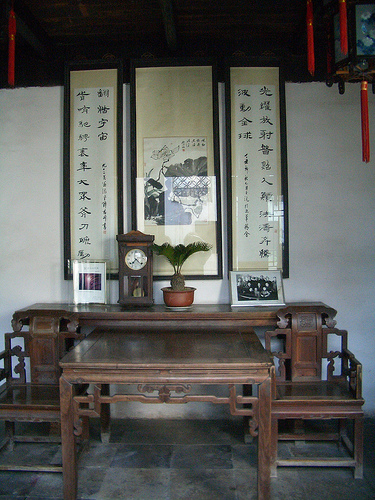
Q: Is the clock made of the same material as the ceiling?
A: Yes, both the clock and the ceiling are made of wood.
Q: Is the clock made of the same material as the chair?
A: Yes, both the clock and the chair are made of wood.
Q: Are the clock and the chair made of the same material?
A: Yes, both the clock and the chair are made of wood.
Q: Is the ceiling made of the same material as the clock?
A: Yes, both the ceiling and the clock are made of wood.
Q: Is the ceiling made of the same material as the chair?
A: Yes, both the ceiling and the chair are made of wood.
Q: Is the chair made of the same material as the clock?
A: Yes, both the chair and the clock are made of wood.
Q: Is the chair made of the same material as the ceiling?
A: Yes, both the chair and the ceiling are made of wood.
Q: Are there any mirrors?
A: No, there are no mirrors.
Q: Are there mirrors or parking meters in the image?
A: No, there are no mirrors or parking meters.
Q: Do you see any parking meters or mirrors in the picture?
A: No, there are no mirrors or parking meters.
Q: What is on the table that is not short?
A: The plant is on the table.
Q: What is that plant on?
A: The plant is on the table.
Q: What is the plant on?
A: The plant is on the table.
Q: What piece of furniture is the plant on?
A: The plant is on the table.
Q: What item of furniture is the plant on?
A: The plant is on the table.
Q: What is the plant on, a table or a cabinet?
A: The plant is on a table.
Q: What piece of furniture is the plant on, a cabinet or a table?
A: The plant is on a table.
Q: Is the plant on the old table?
A: Yes, the plant is on the table.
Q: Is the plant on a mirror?
A: No, the plant is on the table.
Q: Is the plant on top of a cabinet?
A: No, the plant is on top of a table.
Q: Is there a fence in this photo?
A: No, there are no fences.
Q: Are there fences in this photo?
A: No, there are no fences.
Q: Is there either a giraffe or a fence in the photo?
A: No, there are no fences or giraffes.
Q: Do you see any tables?
A: Yes, there is a table.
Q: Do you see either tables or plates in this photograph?
A: Yes, there is a table.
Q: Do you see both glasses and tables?
A: No, there is a table but no glasses.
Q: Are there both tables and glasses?
A: No, there is a table but no glasses.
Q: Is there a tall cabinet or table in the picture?
A: Yes, there is a tall table.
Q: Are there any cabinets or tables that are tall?
A: Yes, the table is tall.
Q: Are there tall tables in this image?
A: Yes, there is a tall table.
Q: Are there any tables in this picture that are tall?
A: Yes, there is a table that is tall.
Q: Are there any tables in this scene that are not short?
A: Yes, there is a tall table.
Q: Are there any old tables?
A: Yes, there is an old table.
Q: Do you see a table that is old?
A: Yes, there is a table that is old.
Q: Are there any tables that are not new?
A: Yes, there is a old table.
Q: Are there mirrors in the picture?
A: No, there are no mirrors.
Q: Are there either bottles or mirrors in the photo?
A: No, there are no mirrors or bottles.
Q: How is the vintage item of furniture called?
A: The piece of furniture is a table.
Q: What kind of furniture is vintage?
A: The furniture is a table.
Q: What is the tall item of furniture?
A: The piece of furniture is a table.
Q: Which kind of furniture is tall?
A: The furniture is a table.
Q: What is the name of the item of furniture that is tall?
A: The piece of furniture is a table.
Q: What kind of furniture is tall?
A: The furniture is a table.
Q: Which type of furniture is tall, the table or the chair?
A: The table is tall.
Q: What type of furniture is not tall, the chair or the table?
A: The chair is not tall.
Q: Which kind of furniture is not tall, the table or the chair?
A: The chair is not tall.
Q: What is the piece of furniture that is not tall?
A: The piece of furniture is a chair.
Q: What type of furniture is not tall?
A: The furniture is a chair.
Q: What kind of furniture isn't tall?
A: The furniture is a chair.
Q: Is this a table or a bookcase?
A: This is a table.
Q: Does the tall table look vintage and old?
A: Yes, the table is vintage and old.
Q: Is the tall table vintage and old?
A: Yes, the table is vintage and old.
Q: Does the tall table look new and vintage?
A: No, the table is vintage but old.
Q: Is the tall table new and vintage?
A: No, the table is vintage but old.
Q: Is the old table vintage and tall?
A: Yes, the table is vintage and tall.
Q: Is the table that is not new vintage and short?
A: No, the table is vintage but tall.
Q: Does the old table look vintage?
A: Yes, the table is vintage.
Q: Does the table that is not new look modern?
A: No, the table is vintage.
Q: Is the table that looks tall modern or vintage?
A: The table is vintage.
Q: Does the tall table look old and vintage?
A: Yes, the table is old and vintage.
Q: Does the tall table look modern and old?
A: No, the table is old but vintage.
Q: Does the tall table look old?
A: Yes, the table is old.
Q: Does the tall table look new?
A: No, the table is old.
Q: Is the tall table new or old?
A: The table is old.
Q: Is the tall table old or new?
A: The table is old.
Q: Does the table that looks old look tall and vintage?
A: Yes, the table is tall and vintage.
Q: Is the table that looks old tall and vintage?
A: Yes, the table is tall and vintage.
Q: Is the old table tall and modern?
A: No, the table is tall but vintage.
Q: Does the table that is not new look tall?
A: Yes, the table is tall.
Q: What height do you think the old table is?
A: The table is tall.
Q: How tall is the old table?
A: The table is tall.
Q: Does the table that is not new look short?
A: No, the table is tall.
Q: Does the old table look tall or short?
A: The table is tall.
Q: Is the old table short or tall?
A: The table is tall.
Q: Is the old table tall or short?
A: The table is tall.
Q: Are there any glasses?
A: No, there are no glasses.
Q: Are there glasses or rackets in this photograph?
A: No, there are no glasses or rackets.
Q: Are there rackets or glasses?
A: No, there are no glasses or rackets.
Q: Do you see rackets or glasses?
A: No, there are no glasses or rackets.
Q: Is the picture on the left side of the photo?
A: Yes, the picture is on the left of the image.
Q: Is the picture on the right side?
A: No, the picture is on the left of the image.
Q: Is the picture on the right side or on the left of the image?
A: The picture is on the left of the image.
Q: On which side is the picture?
A: The picture is on the left of the image.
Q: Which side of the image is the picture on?
A: The picture is on the left of the image.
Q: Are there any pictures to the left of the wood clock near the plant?
A: Yes, there is a picture to the left of the clock.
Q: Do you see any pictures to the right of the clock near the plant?
A: No, the picture is to the left of the clock.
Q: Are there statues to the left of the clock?
A: No, there is a picture to the left of the clock.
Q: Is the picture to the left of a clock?
A: Yes, the picture is to the left of a clock.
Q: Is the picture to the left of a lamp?
A: No, the picture is to the left of a clock.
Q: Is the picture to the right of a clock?
A: No, the picture is to the left of a clock.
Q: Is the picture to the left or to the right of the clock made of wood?
A: The picture is to the left of the clock.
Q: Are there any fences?
A: No, there are no fences.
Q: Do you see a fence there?
A: No, there are no fences.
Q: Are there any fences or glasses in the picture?
A: No, there are no fences or glasses.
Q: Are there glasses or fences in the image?
A: No, there are no fences or glasses.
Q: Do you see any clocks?
A: Yes, there is a clock.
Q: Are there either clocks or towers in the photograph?
A: Yes, there is a clock.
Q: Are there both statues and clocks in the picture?
A: No, there is a clock but no statues.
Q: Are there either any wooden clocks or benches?
A: Yes, there is a wood clock.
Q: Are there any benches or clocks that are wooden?
A: Yes, the clock is wooden.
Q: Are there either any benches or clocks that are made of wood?
A: Yes, the clock is made of wood.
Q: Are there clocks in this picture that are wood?
A: Yes, there is a wood clock.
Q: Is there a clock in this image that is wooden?
A: Yes, there is a clock that is wooden.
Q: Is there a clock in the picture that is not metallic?
A: Yes, there is a wooden clock.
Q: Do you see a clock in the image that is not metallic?
A: Yes, there is a wooden clock.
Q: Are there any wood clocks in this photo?
A: Yes, there is a clock that is made of wood.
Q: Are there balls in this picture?
A: No, there are no balls.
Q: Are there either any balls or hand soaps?
A: No, there are no balls or hand soaps.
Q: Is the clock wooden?
A: Yes, the clock is wooden.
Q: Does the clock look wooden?
A: Yes, the clock is wooden.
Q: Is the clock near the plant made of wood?
A: Yes, the clock is made of wood.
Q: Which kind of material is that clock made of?
A: The clock is made of wood.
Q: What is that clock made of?
A: The clock is made of wood.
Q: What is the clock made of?
A: The clock is made of wood.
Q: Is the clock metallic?
A: No, the clock is wooden.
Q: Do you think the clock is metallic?
A: No, the clock is wooden.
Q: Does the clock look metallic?
A: No, the clock is wooden.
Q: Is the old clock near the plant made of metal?
A: No, the clock is made of wood.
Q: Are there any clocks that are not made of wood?
A: No, there is a clock but it is made of wood.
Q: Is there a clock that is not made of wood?
A: No, there is a clock but it is made of wood.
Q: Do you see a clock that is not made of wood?
A: No, there is a clock but it is made of wood.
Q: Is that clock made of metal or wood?
A: The clock is made of wood.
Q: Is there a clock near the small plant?
A: Yes, there is a clock near the plant.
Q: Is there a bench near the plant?
A: No, there is a clock near the plant.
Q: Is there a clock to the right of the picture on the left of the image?
A: Yes, there is a clock to the right of the picture.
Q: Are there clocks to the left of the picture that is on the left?
A: No, the clock is to the right of the picture.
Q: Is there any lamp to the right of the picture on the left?
A: No, there is a clock to the right of the picture.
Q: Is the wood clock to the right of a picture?
A: Yes, the clock is to the right of a picture.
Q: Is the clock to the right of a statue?
A: No, the clock is to the right of a picture.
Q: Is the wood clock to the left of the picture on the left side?
A: No, the clock is to the right of the picture.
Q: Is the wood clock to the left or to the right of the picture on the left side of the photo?
A: The clock is to the right of the picture.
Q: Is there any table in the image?
A: Yes, there is a table.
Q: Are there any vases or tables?
A: Yes, there is a table.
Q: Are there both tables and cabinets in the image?
A: No, there is a table but no cabinets.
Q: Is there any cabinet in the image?
A: No, there are no cabinets.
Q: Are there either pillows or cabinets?
A: No, there are no cabinets or pillows.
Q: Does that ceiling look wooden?
A: Yes, the ceiling is wooden.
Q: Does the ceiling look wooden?
A: Yes, the ceiling is wooden.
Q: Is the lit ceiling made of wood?
A: Yes, the ceiling is made of wood.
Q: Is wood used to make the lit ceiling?
A: Yes, the ceiling is made of wood.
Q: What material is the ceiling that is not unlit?
A: The ceiling is made of wood.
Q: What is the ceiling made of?
A: The ceiling is made of wood.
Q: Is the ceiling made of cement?
A: No, the ceiling is made of wood.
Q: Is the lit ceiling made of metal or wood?
A: The ceiling is made of wood.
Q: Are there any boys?
A: No, there are no boys.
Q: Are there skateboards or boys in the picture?
A: No, there are no boys or skateboards.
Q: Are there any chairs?
A: Yes, there is a chair.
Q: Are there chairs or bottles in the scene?
A: Yes, there is a chair.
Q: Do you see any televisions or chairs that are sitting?
A: Yes, the chair is sitting.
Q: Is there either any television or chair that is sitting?
A: Yes, the chair is sitting.